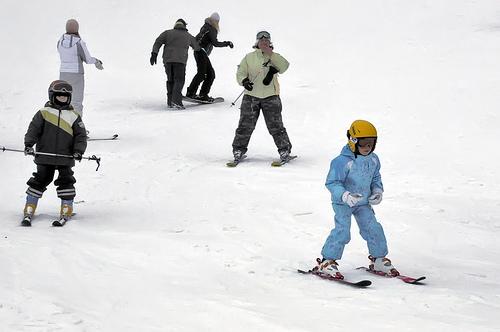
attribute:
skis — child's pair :
[285, 250, 427, 288]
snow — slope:
[138, 197, 270, 304]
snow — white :
[92, 169, 326, 284]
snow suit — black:
[22, 71, 114, 244]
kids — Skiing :
[338, 101, 416, 269]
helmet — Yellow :
[343, 120, 377, 155]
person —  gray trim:
[51, 22, 86, 104]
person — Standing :
[149, 19, 201, 109]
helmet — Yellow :
[342, 116, 380, 156]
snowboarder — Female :
[182, 6, 254, 118]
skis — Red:
[284, 247, 426, 307]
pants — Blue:
[306, 207, 431, 279]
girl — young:
[311, 117, 400, 280]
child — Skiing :
[0, 72, 118, 247]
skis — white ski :
[298, 275, 429, 286]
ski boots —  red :
[313, 258, 398, 275]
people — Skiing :
[124, 9, 320, 173]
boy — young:
[303, 119, 405, 276]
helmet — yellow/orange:
[325, 114, 392, 222]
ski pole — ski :
[3, 146, 101, 171]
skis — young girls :
[309, 272, 423, 287]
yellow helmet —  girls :
[346, 119, 377, 157]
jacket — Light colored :
[235, 48, 289, 96]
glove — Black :
[242, 77, 254, 89]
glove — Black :
[262, 64, 279, 84]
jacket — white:
[52, 34, 102, 82]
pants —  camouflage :
[226, 96, 299, 162]